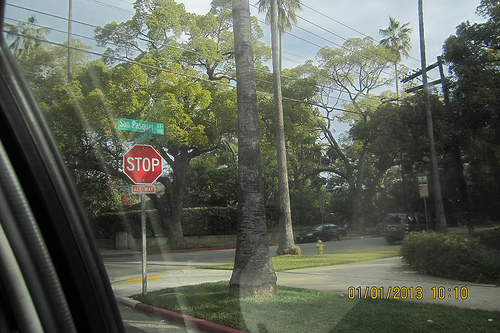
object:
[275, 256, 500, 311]
sidewalk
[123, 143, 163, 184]
sign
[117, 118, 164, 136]
sign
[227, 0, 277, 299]
tree trunk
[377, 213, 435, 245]
suv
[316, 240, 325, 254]
fire hydrant